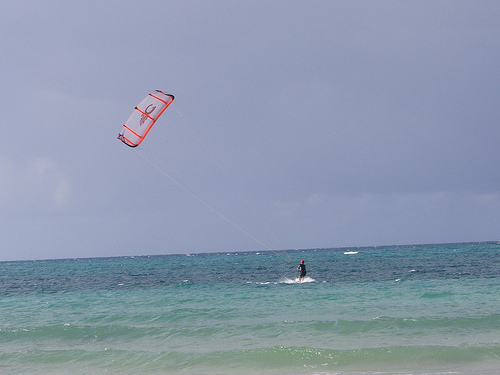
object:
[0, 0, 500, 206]
sky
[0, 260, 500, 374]
ocean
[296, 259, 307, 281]
man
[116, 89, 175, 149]
parasail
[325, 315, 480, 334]
wave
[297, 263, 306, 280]
wetsuit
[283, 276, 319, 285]
foam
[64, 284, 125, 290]
wave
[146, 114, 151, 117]
orange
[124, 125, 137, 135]
stripe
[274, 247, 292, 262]
string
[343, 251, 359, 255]
foam